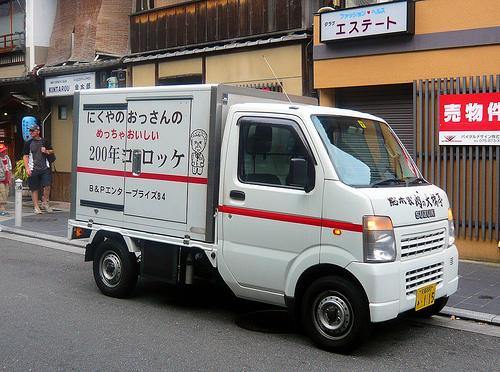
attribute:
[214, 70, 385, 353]
side — passengers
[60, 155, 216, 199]
stripes — red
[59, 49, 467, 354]
truck — white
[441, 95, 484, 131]
lettering — white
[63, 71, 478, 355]
truck — white, vehicle, side 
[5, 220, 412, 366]
asphalt —  black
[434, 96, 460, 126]
lettering — white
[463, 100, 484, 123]
lettering — white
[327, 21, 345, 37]
lettering — black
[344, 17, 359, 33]
lettering — black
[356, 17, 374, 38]
lettering — black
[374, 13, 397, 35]
lettering — black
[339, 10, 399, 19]
lettering — blue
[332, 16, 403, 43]
lettering — red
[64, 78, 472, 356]
vehicle — white food delivery 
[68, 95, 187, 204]
lettering — chinese 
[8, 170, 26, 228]
pole — white 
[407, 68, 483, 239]
gate — metal 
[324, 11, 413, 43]
sign — white rectangle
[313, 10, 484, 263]
building — orange 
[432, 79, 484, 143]
sign — white   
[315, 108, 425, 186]
windshield — glass  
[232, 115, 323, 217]
window — passengers, front passenger side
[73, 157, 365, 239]
stripe — red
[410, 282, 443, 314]
license plate — yellow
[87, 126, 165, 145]
writing — asian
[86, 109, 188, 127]
black lettering — yellow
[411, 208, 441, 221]
brand — vehicle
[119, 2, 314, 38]
bars — metal 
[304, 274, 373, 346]
right wheels — front right  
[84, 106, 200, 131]
text — side 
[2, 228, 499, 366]
paved street — black paved 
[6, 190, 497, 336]
concrete sidewalk — gray concrete 